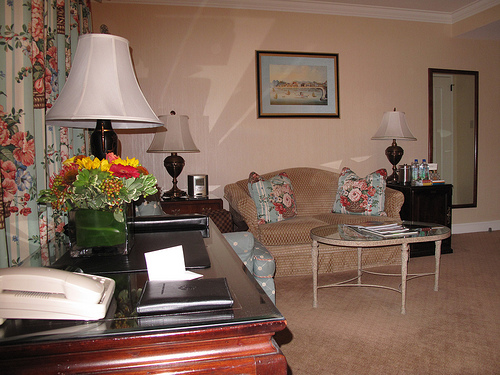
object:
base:
[0, 271, 116, 321]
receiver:
[0, 267, 115, 321]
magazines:
[345, 220, 399, 229]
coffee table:
[309, 219, 452, 314]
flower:
[109, 163, 141, 178]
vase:
[74, 208, 128, 246]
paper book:
[138, 276, 233, 312]